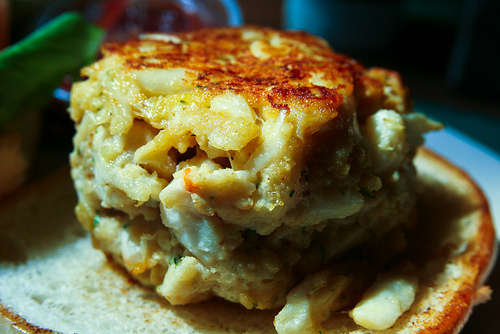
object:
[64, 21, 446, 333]
crab cake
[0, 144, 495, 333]
bread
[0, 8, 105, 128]
napkin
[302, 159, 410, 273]
shadow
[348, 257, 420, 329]
onion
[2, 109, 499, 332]
plate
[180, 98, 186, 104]
spice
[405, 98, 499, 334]
table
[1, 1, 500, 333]
picture